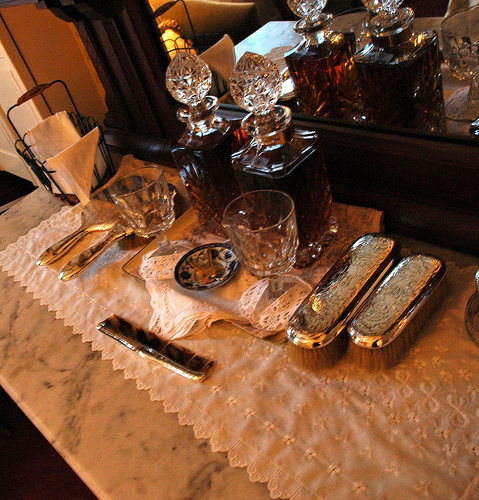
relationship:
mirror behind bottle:
[147, 0, 479, 157] [163, 50, 237, 237]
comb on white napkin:
[93, 306, 225, 396] [24, 216, 418, 400]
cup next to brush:
[221, 187, 312, 332] [272, 221, 401, 376]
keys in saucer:
[181, 244, 228, 286] [174, 241, 239, 291]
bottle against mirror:
[227, 50, 339, 269] [147, 0, 479, 157]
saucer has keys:
[174, 241, 239, 291] [181, 250, 220, 286]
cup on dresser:
[221, 187, 312, 332] [2, 0, 476, 496]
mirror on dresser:
[153, 3, 477, 142] [2, 154, 476, 498]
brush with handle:
[105, 191, 176, 251] [61, 218, 128, 280]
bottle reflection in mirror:
[287, 2, 444, 135] [147, 0, 479, 157]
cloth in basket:
[29, 117, 104, 203] [8, 74, 112, 200]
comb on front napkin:
[93, 306, 225, 396] [128, 214, 317, 363]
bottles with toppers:
[166, 45, 251, 240] [155, 46, 297, 141]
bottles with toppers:
[273, 0, 457, 136] [267, 0, 415, 41]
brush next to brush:
[345, 250, 446, 371] [285, 227, 399, 372]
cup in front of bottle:
[221, 187, 312, 332] [227, 50, 339, 269]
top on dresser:
[12, 342, 102, 454] [23, 211, 463, 475]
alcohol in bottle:
[174, 125, 334, 250] [227, 50, 339, 269]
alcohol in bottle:
[174, 125, 334, 250] [165, 51, 247, 239]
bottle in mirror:
[347, 0, 446, 125] [102, 8, 460, 126]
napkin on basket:
[23, 109, 107, 208] [6, 79, 119, 204]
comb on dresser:
[94, 312, 217, 385] [46, 1, 470, 264]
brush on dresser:
[341, 250, 447, 371] [20, 189, 452, 445]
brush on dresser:
[285, 227, 399, 372] [20, 189, 452, 445]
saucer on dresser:
[174, 241, 238, 288] [30, 188, 456, 477]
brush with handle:
[58, 181, 188, 286] [72, 241, 110, 283]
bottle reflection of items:
[281, 0, 358, 126] [3, 47, 448, 393]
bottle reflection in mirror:
[281, 0, 358, 126] [147, 0, 479, 157]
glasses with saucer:
[118, 167, 305, 318] [174, 241, 239, 291]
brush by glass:
[285, 227, 411, 372] [123, 171, 185, 242]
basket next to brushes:
[6, 103, 126, 199] [43, 174, 138, 272]